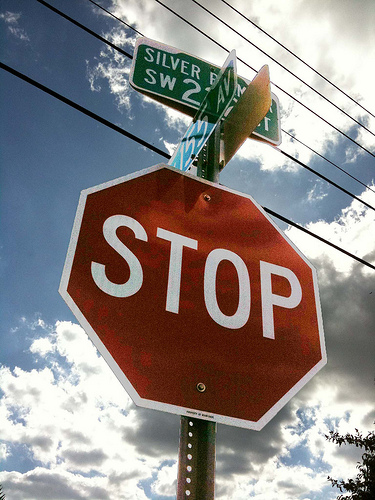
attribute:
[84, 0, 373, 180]
clouds — white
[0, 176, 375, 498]
cloud — white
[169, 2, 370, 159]
clouds — white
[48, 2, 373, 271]
power lines — black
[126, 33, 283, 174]
signs — green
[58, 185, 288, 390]
sign — metal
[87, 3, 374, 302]
clouds — grey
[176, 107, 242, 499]
pole — green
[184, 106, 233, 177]
pole — metal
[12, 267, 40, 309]
clouds — white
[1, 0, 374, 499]
clouds — white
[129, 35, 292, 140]
street sign — green, white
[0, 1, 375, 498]
sky — blue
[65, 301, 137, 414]
edge — white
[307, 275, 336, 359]
edge — white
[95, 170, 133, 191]
edge — white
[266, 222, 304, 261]
edge — white